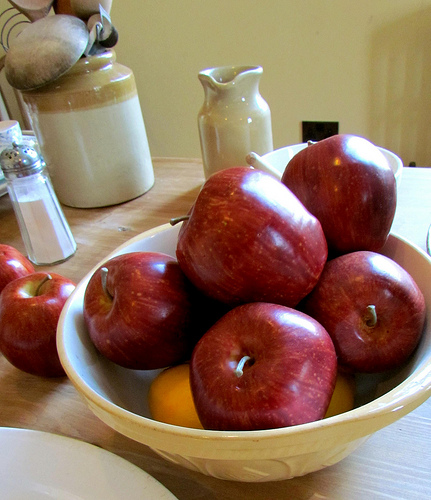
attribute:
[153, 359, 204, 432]
orange — yellow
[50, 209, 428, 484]
bowl — white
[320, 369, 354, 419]
orange — yellow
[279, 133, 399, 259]
apple — red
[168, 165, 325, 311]
apple — red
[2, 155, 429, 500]
table — light, brown, wooden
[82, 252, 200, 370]
apple — red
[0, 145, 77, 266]
salt shaker — white, glass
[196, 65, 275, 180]
pitcher — cream-colored, ceramic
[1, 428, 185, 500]
plate — white, round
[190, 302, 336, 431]
apple — red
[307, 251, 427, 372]
apple — red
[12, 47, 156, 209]
jar — light, ceramic, antique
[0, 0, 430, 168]
wall — mustard-colored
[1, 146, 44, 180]
cap — silver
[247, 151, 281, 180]
handle — wooden